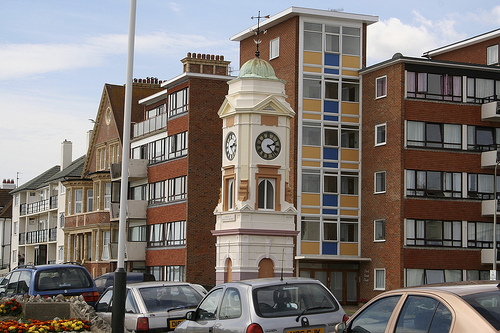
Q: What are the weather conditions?
A: It is cloudy.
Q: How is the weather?
A: It is cloudy.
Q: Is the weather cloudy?
A: Yes, it is cloudy.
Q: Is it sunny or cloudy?
A: It is cloudy.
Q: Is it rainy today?
A: No, it is cloudy.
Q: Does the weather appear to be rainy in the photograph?
A: No, it is cloudy.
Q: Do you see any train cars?
A: No, there are no train cars.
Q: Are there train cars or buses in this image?
A: No, there are no train cars or buses.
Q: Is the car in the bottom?
A: Yes, the car is in the bottom of the image.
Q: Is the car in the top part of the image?
A: No, the car is in the bottom of the image.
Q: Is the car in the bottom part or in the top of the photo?
A: The car is in the bottom of the image.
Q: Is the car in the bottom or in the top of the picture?
A: The car is in the bottom of the image.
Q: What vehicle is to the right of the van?
A: The vehicle is a car.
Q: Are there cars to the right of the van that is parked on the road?
A: Yes, there is a car to the right of the van.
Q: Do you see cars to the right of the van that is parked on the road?
A: Yes, there is a car to the right of the van.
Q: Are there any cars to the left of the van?
A: No, the car is to the right of the van.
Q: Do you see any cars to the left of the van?
A: No, the car is to the right of the van.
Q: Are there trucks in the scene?
A: No, there are no trucks.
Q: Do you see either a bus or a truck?
A: No, there are no trucks or buses.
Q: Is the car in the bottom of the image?
A: Yes, the car is in the bottom of the image.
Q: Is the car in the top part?
A: No, the car is in the bottom of the image.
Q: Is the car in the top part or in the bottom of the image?
A: The car is in the bottom of the image.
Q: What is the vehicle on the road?
A: The vehicle is a car.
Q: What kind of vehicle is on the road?
A: The vehicle is a car.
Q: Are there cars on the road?
A: Yes, there is a car on the road.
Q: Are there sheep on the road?
A: No, there is a car on the road.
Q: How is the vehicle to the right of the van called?
A: The vehicle is a car.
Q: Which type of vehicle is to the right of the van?
A: The vehicle is a car.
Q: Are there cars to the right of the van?
A: Yes, there is a car to the right of the van.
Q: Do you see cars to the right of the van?
A: Yes, there is a car to the right of the van.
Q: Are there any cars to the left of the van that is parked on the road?
A: No, the car is to the right of the van.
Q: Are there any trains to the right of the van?
A: No, there is a car to the right of the van.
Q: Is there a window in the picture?
A: Yes, there is a window.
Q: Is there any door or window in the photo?
A: Yes, there is a window.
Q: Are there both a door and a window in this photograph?
A: Yes, there are both a window and a door.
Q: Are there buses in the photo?
A: No, there are no buses.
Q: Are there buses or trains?
A: No, there are no buses or trains.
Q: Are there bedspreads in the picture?
A: No, there are no bedspreads.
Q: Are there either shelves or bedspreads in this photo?
A: No, there are no bedspreads or shelves.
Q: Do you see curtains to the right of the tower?
A: Yes, there is a curtain to the right of the tower.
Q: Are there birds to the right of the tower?
A: No, there is a curtain to the right of the tower.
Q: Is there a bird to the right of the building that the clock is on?
A: No, there is a curtain to the right of the tower.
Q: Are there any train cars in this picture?
A: No, there are no train cars.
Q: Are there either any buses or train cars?
A: No, there are no train cars or buses.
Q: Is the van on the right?
A: No, the van is on the left of the image.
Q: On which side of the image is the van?
A: The van is on the left of the image.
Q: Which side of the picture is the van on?
A: The van is on the left of the image.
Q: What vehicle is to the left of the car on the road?
A: The vehicle is a van.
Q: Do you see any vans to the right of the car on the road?
A: No, the van is to the left of the car.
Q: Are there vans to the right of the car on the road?
A: No, the van is to the left of the car.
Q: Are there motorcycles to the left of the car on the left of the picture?
A: No, there is a van to the left of the car.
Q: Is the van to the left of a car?
A: Yes, the van is to the left of a car.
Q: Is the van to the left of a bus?
A: No, the van is to the left of a car.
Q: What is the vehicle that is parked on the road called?
A: The vehicle is a van.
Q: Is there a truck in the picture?
A: No, there are no trucks.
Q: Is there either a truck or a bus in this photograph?
A: No, there are no trucks or buses.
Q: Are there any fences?
A: Yes, there is a fence.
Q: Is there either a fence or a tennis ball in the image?
A: Yes, there is a fence.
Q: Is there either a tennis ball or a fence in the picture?
A: Yes, there is a fence.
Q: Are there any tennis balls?
A: No, there are no tennis balls.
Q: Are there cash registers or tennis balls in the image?
A: No, there are no tennis balls or cash registers.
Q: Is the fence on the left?
A: Yes, the fence is on the left of the image.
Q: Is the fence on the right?
A: No, the fence is on the left of the image.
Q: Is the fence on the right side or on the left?
A: The fence is on the left of the image.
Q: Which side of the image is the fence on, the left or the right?
A: The fence is on the left of the image.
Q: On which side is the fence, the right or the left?
A: The fence is on the left of the image.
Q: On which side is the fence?
A: The fence is on the left of the image.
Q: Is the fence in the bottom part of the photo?
A: Yes, the fence is in the bottom of the image.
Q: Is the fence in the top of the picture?
A: No, the fence is in the bottom of the image.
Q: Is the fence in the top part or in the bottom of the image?
A: The fence is in the bottom of the image.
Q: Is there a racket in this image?
A: No, there are no rackets.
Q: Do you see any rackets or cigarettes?
A: No, there are no rackets or cigarettes.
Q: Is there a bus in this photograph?
A: No, there are no buses.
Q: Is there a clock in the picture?
A: Yes, there is a clock.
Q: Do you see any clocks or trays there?
A: Yes, there is a clock.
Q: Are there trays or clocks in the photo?
A: Yes, there is a clock.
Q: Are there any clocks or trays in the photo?
A: Yes, there is a clock.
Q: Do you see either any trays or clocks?
A: Yes, there is a clock.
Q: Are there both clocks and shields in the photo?
A: No, there is a clock but no shields.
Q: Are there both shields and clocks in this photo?
A: No, there is a clock but no shields.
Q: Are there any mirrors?
A: No, there are no mirrors.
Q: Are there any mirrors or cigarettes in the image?
A: No, there are no mirrors or cigarettes.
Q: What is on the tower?
A: The clock is on the tower.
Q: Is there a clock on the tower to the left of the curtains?
A: Yes, there is a clock on the tower.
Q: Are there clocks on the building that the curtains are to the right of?
A: Yes, there is a clock on the tower.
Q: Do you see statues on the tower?
A: No, there is a clock on the tower.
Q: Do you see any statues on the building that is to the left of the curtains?
A: No, there is a clock on the tower.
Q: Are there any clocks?
A: Yes, there is a clock.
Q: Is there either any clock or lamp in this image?
A: Yes, there is a clock.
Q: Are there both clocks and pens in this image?
A: No, there is a clock but no pens.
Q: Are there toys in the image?
A: No, there are no toys.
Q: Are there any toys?
A: No, there are no toys.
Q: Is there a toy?
A: No, there are no toys.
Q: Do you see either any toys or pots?
A: No, there are no toys or pots.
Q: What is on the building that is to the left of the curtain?
A: The clock is on the tower.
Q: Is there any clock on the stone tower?
A: Yes, there is a clock on the tower.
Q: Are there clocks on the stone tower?
A: Yes, there is a clock on the tower.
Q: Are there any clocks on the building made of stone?
A: Yes, there is a clock on the tower.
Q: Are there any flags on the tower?
A: No, there is a clock on the tower.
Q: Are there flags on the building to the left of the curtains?
A: No, there is a clock on the tower.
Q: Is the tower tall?
A: Yes, the tower is tall.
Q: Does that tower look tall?
A: Yes, the tower is tall.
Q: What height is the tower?
A: The tower is tall.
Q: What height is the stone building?
A: The tower is tall.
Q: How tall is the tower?
A: The tower is tall.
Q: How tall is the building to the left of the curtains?
A: The tower is tall.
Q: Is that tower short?
A: No, the tower is tall.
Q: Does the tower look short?
A: No, the tower is tall.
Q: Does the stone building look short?
A: No, the tower is tall.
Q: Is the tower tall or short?
A: The tower is tall.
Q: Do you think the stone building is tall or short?
A: The tower is tall.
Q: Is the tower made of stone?
A: Yes, the tower is made of stone.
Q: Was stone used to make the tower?
A: Yes, the tower is made of stone.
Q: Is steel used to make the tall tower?
A: No, the tower is made of stone.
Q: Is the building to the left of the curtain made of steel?
A: No, the tower is made of stone.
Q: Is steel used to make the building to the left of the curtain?
A: No, the tower is made of stone.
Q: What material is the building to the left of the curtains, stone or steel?
A: The tower is made of stone.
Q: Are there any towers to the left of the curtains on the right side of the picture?
A: Yes, there is a tower to the left of the curtains.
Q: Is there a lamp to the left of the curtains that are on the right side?
A: No, there is a tower to the left of the curtains.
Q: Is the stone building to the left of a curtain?
A: Yes, the tower is to the left of a curtain.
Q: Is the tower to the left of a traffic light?
A: No, the tower is to the left of a curtain.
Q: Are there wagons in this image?
A: No, there are no wagons.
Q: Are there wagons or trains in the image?
A: No, there are no wagons or trains.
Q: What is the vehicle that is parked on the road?
A: The vehicle is a car.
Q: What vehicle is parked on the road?
A: The vehicle is a car.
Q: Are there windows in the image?
A: Yes, there is a window.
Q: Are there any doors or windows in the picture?
A: Yes, there is a window.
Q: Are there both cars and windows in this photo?
A: Yes, there are both a window and a car.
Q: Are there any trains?
A: No, there are no trains.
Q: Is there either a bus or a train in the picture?
A: No, there are no trains or buses.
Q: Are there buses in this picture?
A: No, there are no buses.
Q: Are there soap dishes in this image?
A: No, there are no soap dishes.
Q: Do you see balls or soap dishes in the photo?
A: No, there are no soap dishes or balls.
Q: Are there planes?
A: No, there are no planes.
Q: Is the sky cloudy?
A: Yes, the sky is cloudy.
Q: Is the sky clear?
A: No, the sky is cloudy.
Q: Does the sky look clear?
A: No, the sky is cloudy.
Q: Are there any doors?
A: Yes, there is a door.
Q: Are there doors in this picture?
A: Yes, there is a door.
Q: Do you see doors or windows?
A: Yes, there is a door.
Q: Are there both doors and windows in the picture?
A: Yes, there are both a door and a window.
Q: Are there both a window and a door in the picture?
A: Yes, there are both a door and a window.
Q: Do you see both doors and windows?
A: Yes, there are both a door and a window.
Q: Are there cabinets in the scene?
A: No, there are no cabinets.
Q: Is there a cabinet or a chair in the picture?
A: No, there are no cabinets or chairs.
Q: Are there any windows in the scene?
A: Yes, there are windows.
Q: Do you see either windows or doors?
A: Yes, there are windows.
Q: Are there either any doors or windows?
A: Yes, there are windows.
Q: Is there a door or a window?
A: Yes, there are windows.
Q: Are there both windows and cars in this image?
A: Yes, there are both windows and a car.